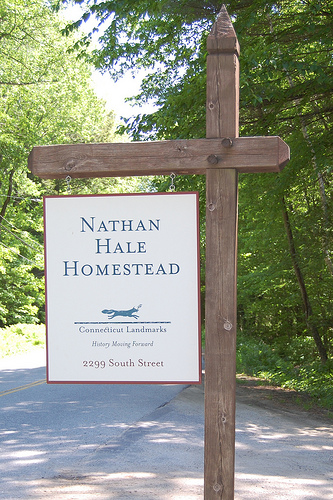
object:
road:
[0, 338, 332, 500]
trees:
[0, 0, 134, 332]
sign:
[43, 193, 207, 387]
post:
[201, 5, 234, 499]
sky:
[50, 0, 263, 131]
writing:
[53, 212, 188, 374]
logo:
[71, 303, 172, 326]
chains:
[168, 173, 178, 196]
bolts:
[205, 153, 218, 169]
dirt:
[247, 373, 313, 414]